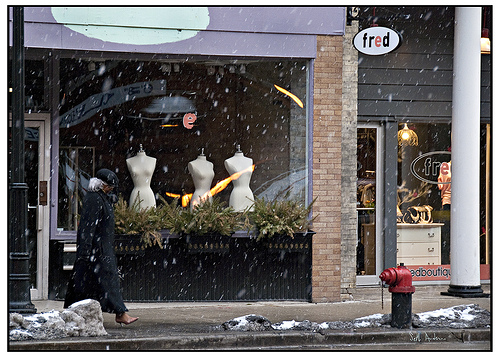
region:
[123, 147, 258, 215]
three dressmaker's dummies in store window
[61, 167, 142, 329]
gray haired woman walking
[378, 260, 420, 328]
red and black fire hydrant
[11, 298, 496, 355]
melting snow on the sidewalk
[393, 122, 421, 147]
chandelier inside the store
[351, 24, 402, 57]
sign for the store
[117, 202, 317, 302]
black fence with plants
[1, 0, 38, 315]
black streetlight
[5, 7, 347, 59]
purple and white awning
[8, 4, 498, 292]
storefront for fred's boutique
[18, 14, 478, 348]
the snow is falling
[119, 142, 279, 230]
three mannequins in the window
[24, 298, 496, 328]
the snow on the sidewalk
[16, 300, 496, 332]
the snow is dirty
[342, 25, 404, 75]
the sign is hanging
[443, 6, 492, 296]
the large white column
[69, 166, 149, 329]
the woman on the sidewalk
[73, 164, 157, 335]
the woman is walking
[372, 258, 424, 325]
the fire hydrant on the sidewalk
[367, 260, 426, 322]
the hydrant is red and black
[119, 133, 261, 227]
three mannequins in a storefront window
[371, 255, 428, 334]
black and red fire hydrant on a curb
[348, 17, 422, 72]
black, orange, and white fred storefront sign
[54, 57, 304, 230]
storefront display window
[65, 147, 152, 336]
woman walking on a sidewalk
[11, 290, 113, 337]
pile of dirty snow on a street sidewalk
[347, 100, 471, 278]
glass door and window storefront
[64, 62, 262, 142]
reflection in a glass storefront window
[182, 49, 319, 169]
snow falling in the air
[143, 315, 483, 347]
curb of a sidewalk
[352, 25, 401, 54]
white shop sign that reads "fred"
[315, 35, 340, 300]
red brick wall facing the sidewalk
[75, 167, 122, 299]
woman walking on the sidewalk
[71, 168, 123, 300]
woman walking by some shops in the snow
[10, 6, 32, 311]
black lamp post on the sidewalk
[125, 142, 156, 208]
bare white storefront mannequin close to the door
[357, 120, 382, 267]
door of fred boutique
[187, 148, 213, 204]
bare mannequin in the center of the display window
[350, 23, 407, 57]
White sign with black and orange letters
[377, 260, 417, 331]
Fire hydrant with red top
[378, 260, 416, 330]
Fire hydrant with black base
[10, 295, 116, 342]
Pile of dirty snow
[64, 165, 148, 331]
Woman walking on sidewalk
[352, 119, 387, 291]
Entry door to a store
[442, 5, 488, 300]
White pole with black base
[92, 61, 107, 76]
Snowflake falling from the sky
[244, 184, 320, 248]
Potted plant in front of a window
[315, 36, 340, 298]
Red brick wall